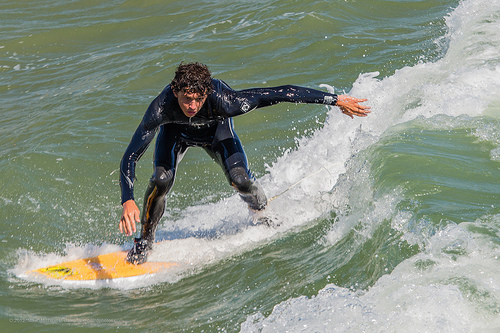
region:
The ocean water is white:
[237, 273, 497, 329]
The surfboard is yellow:
[15, 235, 220, 280]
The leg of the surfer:
[131, 161, 171, 238]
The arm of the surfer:
[115, 101, 165, 236]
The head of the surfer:
[165, 56, 216, 116]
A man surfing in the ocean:
[20, 55, 382, 290]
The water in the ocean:
[6, 5, 111, 205]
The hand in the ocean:
[330, 85, 375, 120]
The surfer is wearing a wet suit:
[77, 47, 360, 280]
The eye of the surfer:
[179, 91, 194, 106]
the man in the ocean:
[58, 65, 385, 277]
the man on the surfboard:
[16, 33, 381, 282]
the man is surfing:
[22, 54, 366, 286]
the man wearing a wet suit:
[83, 41, 368, 251]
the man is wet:
[62, 52, 409, 249]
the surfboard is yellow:
[16, 185, 329, 298]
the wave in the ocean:
[272, 62, 479, 329]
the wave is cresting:
[296, 53, 491, 311]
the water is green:
[33, 27, 130, 90]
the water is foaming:
[300, 61, 495, 331]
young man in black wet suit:
[13, 61, 278, 261]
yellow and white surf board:
[6, 214, 191, 306]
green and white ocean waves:
[19, 15, 117, 92]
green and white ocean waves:
[16, 72, 110, 142]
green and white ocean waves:
[8, 132, 99, 216]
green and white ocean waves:
[96, 14, 220, 59]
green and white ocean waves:
[233, 15, 327, 60]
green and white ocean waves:
[388, 27, 472, 122]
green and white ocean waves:
[278, 155, 385, 235]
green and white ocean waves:
[391, 178, 476, 259]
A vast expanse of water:
[4, 3, 495, 330]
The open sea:
[4, 0, 497, 330]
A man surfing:
[46, 66, 353, 284]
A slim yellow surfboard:
[28, 215, 289, 280]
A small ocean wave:
[310, 70, 498, 331]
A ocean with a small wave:
[3, 3, 494, 332]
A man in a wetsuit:
[117, 65, 371, 262]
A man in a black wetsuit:
[118, 65, 375, 263]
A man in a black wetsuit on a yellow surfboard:
[34, 62, 370, 282]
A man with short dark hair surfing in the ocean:
[32, 66, 372, 282]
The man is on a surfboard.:
[23, 42, 395, 302]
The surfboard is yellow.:
[19, 55, 385, 297]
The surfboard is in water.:
[20, 28, 388, 303]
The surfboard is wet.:
[21, 48, 383, 300]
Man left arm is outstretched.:
[111, 25, 381, 286]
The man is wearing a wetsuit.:
[110, 46, 386, 283]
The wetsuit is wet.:
[105, 47, 375, 274]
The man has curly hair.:
[112, 53, 382, 274]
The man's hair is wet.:
[108, 40, 375, 276]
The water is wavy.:
[1, 0, 496, 330]